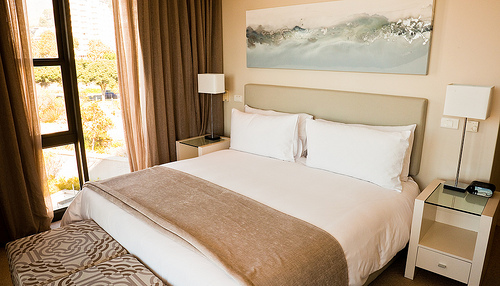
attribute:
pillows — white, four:
[226, 103, 414, 193]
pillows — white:
[302, 115, 416, 191]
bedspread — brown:
[96, 164, 279, 282]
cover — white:
[195, 149, 351, 205]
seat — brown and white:
[6, 219, 153, 284]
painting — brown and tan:
[243, 7, 431, 74]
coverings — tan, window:
[114, 2, 219, 162]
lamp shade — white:
[196, 73, 226, 93]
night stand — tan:
[176, 130, 230, 156]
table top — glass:
[184, 135, 220, 145]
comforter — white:
[69, 139, 422, 284]